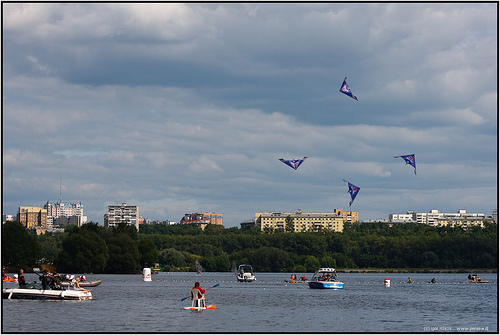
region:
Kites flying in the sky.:
[275, 63, 441, 216]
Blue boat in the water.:
[304, 265, 353, 292]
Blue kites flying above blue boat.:
[261, 64, 433, 294]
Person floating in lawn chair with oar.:
[174, 273, 224, 311]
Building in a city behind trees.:
[3, 159, 497, 252]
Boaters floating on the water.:
[1, 253, 496, 320]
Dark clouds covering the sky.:
[7, 11, 494, 139]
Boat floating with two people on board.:
[1, 265, 92, 304]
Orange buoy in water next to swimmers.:
[379, 271, 449, 295]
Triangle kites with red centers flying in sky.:
[268, 68, 433, 205]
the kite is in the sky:
[271, 144, 314, 176]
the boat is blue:
[319, 282, 336, 290]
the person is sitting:
[193, 287, 206, 302]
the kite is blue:
[346, 185, 360, 198]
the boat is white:
[241, 272, 253, 282]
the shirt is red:
[194, 284, 204, 293]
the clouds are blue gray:
[247, 61, 278, 86]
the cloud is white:
[359, 126, 387, 138]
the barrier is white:
[141, 265, 153, 285]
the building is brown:
[23, 211, 40, 224]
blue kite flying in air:
[393, 152, 418, 177]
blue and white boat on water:
[306, 268, 343, 290]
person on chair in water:
[179, 281, 219, 310]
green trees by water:
[58, 221, 145, 275]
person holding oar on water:
[181, 280, 221, 312]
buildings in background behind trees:
[15, 198, 84, 230]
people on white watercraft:
[6, 267, 91, 305]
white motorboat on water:
[236, 262, 258, 284]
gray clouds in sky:
[68, 18, 233, 102]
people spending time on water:
[187, 260, 344, 325]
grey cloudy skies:
[4, 0, 499, 220]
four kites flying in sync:
[277, 76, 418, 207]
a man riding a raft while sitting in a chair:
[180, 280, 215, 312]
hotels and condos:
[0, 203, 499, 236]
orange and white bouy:
[383, 278, 392, 285]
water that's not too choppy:
[5, 272, 497, 330]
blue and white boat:
[308, 267, 346, 289]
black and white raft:
[2, 269, 93, 301]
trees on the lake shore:
[3, 217, 495, 274]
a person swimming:
[404, 275, 416, 287]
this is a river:
[26, 19, 413, 311]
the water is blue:
[103, 300, 163, 334]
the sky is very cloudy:
[48, 29, 243, 154]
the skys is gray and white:
[54, 36, 261, 158]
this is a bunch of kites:
[277, 62, 479, 194]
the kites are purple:
[228, 76, 464, 238]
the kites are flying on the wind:
[283, 58, 440, 243]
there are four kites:
[241, 55, 491, 269]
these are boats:
[44, 253, 234, 328]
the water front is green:
[97, 203, 272, 247]